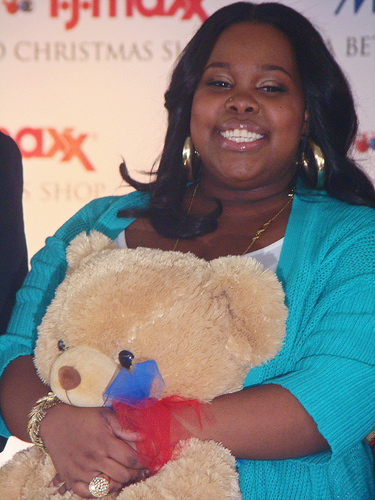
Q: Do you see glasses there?
A: No, there are no glasses.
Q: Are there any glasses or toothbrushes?
A: No, there are no glasses or toothbrushes.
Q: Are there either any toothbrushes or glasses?
A: No, there are no glasses or toothbrushes.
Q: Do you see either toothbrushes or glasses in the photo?
A: No, there are no glasses or toothbrushes.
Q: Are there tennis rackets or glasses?
A: No, there are no glasses or tennis rackets.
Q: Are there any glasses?
A: No, there are no glasses.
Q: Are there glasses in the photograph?
A: No, there are no glasses.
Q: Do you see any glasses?
A: No, there are no glasses.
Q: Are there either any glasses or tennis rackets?
A: No, there are no glasses or tennis rackets.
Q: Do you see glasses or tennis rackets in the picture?
A: No, there are no glasses or tennis rackets.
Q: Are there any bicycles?
A: No, there are no bicycles.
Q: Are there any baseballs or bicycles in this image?
A: No, there are no bicycles or baseballs.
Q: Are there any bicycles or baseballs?
A: No, there are no bicycles or baseballs.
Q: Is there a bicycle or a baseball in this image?
A: No, there are no bicycles or baseballs.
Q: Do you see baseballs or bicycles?
A: No, there are no bicycles or baseballs.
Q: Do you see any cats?
A: No, there are no cats.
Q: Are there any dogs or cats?
A: No, there are no cats or dogs.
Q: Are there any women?
A: Yes, there is a woman.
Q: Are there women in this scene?
A: Yes, there is a woman.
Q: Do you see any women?
A: Yes, there is a woman.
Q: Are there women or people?
A: Yes, there is a woman.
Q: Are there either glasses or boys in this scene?
A: No, there are no glasses or boys.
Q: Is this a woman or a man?
A: This is a woman.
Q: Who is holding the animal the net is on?
A: The woman is holding the bear.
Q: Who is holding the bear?
A: The woman is holding the bear.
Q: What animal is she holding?
A: The woman is holding the bear.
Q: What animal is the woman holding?
A: The woman is holding the bear.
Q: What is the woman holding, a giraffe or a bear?
A: The woman is holding a bear.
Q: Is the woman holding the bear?
A: Yes, the woman is holding the bear.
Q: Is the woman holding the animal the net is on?
A: Yes, the woman is holding the bear.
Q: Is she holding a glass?
A: No, the woman is holding the bear.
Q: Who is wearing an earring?
A: The woman is wearing an earring.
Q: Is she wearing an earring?
A: Yes, the woman is wearing an earring.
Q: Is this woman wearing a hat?
A: No, the woman is wearing an earring.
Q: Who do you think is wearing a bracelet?
A: The woman is wearing a bracelet.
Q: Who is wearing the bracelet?
A: The woman is wearing a bracelet.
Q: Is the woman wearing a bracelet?
A: Yes, the woman is wearing a bracelet.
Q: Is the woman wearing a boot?
A: No, the woman is wearing a bracelet.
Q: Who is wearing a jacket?
A: The woman is wearing a jacket.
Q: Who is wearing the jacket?
A: The woman is wearing a jacket.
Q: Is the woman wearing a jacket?
A: Yes, the woman is wearing a jacket.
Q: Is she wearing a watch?
A: No, the woman is wearing a jacket.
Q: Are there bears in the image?
A: Yes, there is a bear.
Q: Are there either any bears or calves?
A: Yes, there is a bear.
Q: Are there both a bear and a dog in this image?
A: No, there is a bear but no dogs.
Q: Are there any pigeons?
A: No, there are no pigeons.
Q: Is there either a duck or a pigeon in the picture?
A: No, there are no pigeons or ducks.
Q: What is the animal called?
A: The animal is a bear.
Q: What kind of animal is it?
A: The animal is a bear.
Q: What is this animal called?
A: This is a bear.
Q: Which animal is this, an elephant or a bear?
A: This is a bear.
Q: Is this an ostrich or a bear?
A: This is a bear.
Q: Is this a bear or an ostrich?
A: This is a bear.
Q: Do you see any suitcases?
A: No, there are no suitcases.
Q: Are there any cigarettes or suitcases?
A: No, there are no suitcases or cigarettes.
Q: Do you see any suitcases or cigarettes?
A: No, there are no suitcases or cigarettes.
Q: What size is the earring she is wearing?
A: The earring is large.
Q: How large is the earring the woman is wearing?
A: The earring is large.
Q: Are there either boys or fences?
A: No, there are no boys or fences.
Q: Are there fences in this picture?
A: No, there are no fences.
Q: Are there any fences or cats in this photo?
A: No, there are no fences or cats.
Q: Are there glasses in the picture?
A: No, there are no glasses.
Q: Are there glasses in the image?
A: No, there are no glasses.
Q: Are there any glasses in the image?
A: No, there are no glasses.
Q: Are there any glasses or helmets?
A: No, there are no glasses or helmets.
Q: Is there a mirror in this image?
A: No, there are no mirrors.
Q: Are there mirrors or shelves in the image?
A: No, there are no mirrors or shelves.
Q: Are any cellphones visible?
A: No, there are no cellphones.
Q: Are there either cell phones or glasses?
A: No, there are no cell phones or glasses.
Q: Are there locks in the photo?
A: No, there are no locks.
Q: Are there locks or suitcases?
A: No, there are no locks or suitcases.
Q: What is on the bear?
A: The net is on the bear.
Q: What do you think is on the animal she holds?
A: The net is on the bear.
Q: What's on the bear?
A: The net is on the bear.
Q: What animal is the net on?
A: The net is on the bear.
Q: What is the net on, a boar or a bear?
A: The net is on a bear.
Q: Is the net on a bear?
A: Yes, the net is on a bear.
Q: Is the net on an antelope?
A: No, the net is on a bear.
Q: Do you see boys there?
A: No, there are no boys.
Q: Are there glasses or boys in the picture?
A: No, there are no boys or glasses.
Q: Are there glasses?
A: No, there are no glasses.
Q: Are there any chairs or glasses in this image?
A: No, there are no glasses or chairs.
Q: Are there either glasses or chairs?
A: No, there are no glasses or chairs.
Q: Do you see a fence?
A: No, there are no fences.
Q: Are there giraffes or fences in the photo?
A: No, there are no fences or giraffes.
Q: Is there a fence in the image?
A: No, there are no fences.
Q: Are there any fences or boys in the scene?
A: No, there are no fences or boys.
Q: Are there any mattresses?
A: No, there are no mattresses.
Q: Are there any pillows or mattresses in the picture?
A: No, there are no mattresses or pillows.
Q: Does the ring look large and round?
A: Yes, the ring is large and round.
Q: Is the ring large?
A: Yes, the ring is large.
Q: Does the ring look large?
A: Yes, the ring is large.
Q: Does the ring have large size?
A: Yes, the ring is large.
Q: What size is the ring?
A: The ring is large.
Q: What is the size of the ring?
A: The ring is large.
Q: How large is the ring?
A: The ring is large.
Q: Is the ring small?
A: No, the ring is large.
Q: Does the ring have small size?
A: No, the ring is large.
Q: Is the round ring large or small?
A: The ring is large.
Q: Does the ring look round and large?
A: Yes, the ring is round and large.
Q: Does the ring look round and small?
A: No, the ring is round but large.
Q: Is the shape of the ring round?
A: Yes, the ring is round.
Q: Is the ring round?
A: Yes, the ring is round.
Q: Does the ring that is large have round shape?
A: Yes, the ring is round.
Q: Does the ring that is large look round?
A: Yes, the ring is round.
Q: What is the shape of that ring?
A: The ring is round.